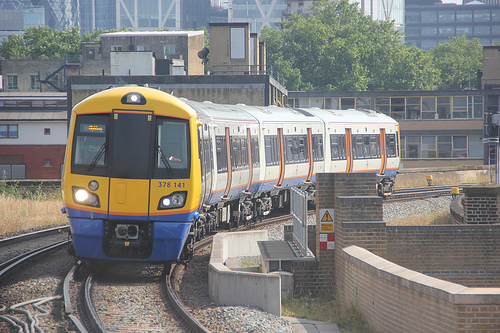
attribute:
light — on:
[71, 182, 102, 209]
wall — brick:
[316, 165, 498, 332]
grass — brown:
[1, 191, 64, 237]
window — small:
[403, 95, 418, 124]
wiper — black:
[87, 138, 112, 173]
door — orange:
[345, 129, 353, 173]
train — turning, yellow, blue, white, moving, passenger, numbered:
[61, 85, 409, 269]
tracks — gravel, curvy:
[62, 259, 210, 331]